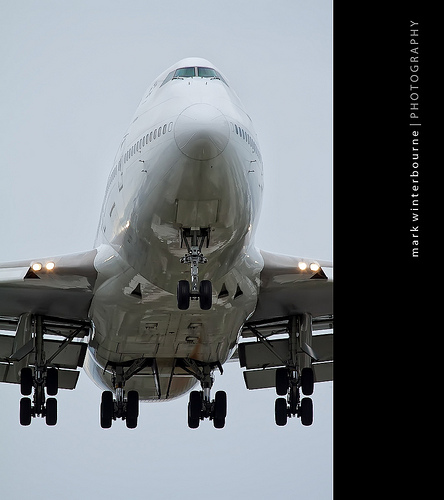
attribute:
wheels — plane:
[172, 274, 219, 307]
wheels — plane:
[264, 358, 316, 426]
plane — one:
[20, 42, 334, 431]